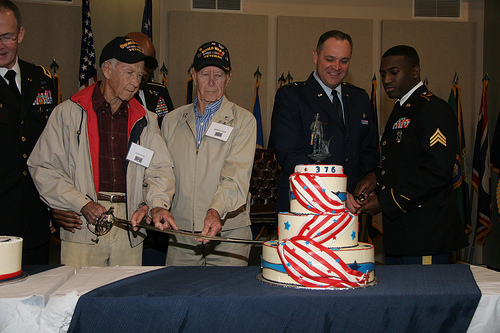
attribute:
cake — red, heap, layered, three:
[258, 161, 378, 291]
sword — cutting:
[92, 205, 264, 243]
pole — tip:
[252, 65, 268, 146]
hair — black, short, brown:
[380, 46, 420, 63]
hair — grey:
[97, 55, 121, 72]